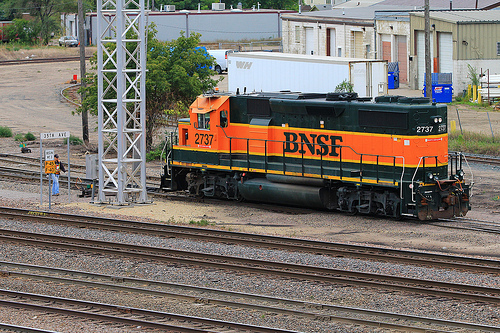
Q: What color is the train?
A: Orange and black.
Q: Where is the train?
A: On the tracks.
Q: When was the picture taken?
A: During the day.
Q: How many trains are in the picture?
A: One.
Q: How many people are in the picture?
A: One.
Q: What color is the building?
A: White.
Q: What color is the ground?
A: Brown.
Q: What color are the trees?
A: Green.